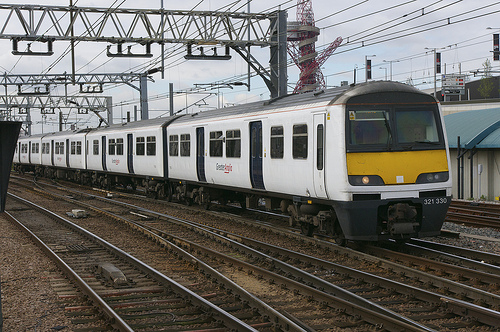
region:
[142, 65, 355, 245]
the train is white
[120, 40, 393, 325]
the train is white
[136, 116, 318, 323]
the train is white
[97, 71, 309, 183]
the train is white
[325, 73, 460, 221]
Front of passenger train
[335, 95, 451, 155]
Windshield of passenger train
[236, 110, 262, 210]
Passenger door of train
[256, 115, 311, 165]
Two passenger windows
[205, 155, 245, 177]
Advertisement on side of passenger train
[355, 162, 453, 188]
Headlights of passenger train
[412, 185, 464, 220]
Number of passenger train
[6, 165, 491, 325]
Railroad tracks for passenger train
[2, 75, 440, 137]
Top of passenger train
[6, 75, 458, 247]
Yellow,white and gray passenger train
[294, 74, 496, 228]
a train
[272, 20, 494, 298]
a train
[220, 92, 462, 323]
a train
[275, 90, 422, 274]
a train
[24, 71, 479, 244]
a very long commuter train coming down the tracks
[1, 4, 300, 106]
an electrical frame going above the tracks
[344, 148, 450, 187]
yellow front panel of the train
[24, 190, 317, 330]
many sets of merging train tracks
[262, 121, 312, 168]
two windows on the first train car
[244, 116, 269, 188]
a door on the side of the first train car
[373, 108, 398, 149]
a windshield wiper on the front of the train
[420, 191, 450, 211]
identification numbers on the front of the train car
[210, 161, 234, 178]
a logo in the middle of the first train car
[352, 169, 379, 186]
a headlamp on the front of the train that is on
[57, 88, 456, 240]
The train is yellow and white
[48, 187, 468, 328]
A multitude of train tracks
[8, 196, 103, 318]
Small rocks surround the train tracks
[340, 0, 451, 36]
White clouds in the sky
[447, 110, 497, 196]
A blue and white building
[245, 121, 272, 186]
A door on the train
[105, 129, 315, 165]
Windows lining the train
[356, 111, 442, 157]
Train conductor's window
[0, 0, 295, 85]
Overhanging metal structure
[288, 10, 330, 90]
Large red and white structure